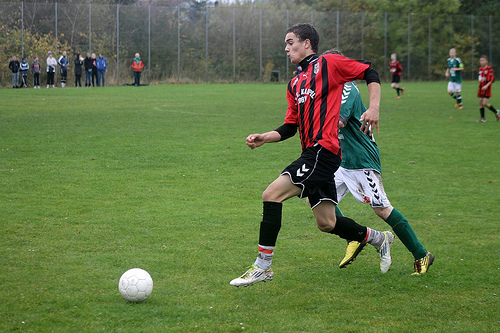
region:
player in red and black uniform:
[230, 20, 395, 289]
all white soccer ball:
[116, 267, 153, 300]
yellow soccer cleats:
[335, 235, 437, 278]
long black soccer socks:
[245, 198, 377, 249]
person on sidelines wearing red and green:
[131, 50, 146, 85]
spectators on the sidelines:
[6, 50, 108, 88]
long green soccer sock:
[385, 207, 428, 259]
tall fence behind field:
[3, 0, 499, 83]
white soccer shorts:
[322, 166, 392, 210]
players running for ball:
[227, 21, 435, 291]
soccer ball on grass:
[105, 260, 184, 306]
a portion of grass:
[52, 185, 164, 246]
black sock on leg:
[262, 202, 277, 242]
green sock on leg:
[394, 215, 417, 244]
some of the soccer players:
[436, 38, 496, 132]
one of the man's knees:
[262, 190, 285, 205]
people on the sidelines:
[4, 50, 73, 80]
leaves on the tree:
[365, 9, 421, 44]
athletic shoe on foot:
[417, 252, 441, 279]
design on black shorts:
[292, 165, 319, 180]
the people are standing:
[10, 48, 227, 115]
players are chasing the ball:
[130, 13, 494, 317]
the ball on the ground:
[68, 242, 188, 332]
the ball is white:
[100, 238, 167, 297]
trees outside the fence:
[129, 5, 250, 75]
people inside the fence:
[2, 27, 498, 283]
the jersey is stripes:
[270, 50, 360, 176]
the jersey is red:
[278, 47, 355, 174]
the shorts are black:
[285, 140, 362, 229]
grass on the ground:
[68, 145, 200, 238]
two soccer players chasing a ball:
[89, 20, 433, 317]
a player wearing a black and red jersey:
[237, 5, 383, 286]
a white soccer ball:
[96, 246, 165, 320]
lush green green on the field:
[59, 125, 209, 220]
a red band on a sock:
[251, 245, 283, 257]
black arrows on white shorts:
[359, 167, 382, 204]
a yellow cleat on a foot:
[343, 241, 369, 273]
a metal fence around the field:
[180, 16, 252, 68]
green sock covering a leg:
[393, 211, 440, 258]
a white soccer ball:
[112, 267, 156, 300]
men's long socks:
[255, 200, 280, 267]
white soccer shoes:
[223, 263, 277, 285]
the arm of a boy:
[316, 55, 379, 131]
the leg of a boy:
[350, 165, 425, 252]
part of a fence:
[150, 5, 180, 82]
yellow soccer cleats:
[334, 233, 366, 268]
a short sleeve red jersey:
[477, 65, 494, 87]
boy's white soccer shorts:
[325, 165, 386, 208]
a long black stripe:
[316, 51, 327, 141]